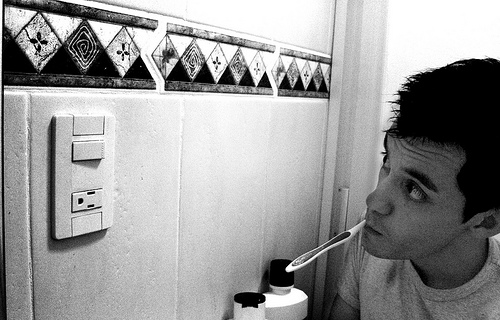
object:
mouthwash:
[258, 258, 306, 320]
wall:
[0, 0, 340, 320]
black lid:
[270, 259, 295, 287]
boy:
[328, 58, 500, 320]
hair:
[381, 58, 500, 226]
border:
[0, 0, 333, 99]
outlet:
[50, 113, 114, 240]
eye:
[380, 151, 392, 172]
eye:
[403, 179, 429, 204]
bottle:
[227, 293, 266, 320]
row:
[0, 9, 333, 100]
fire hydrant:
[285, 219, 366, 273]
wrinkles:
[390, 124, 454, 167]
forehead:
[384, 132, 465, 176]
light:
[51, 113, 114, 241]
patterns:
[0, 9, 333, 99]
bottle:
[262, 259, 306, 320]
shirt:
[334, 224, 500, 320]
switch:
[73, 115, 105, 136]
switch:
[73, 140, 105, 161]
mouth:
[362, 216, 386, 240]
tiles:
[0, 0, 338, 320]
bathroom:
[0, 0, 500, 320]